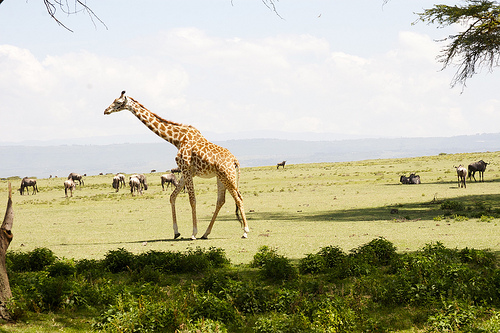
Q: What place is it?
A: It is a field.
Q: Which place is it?
A: It is a field.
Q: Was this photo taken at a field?
A: Yes, it was taken in a field.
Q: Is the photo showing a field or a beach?
A: It is showing a field.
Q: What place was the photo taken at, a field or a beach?
A: It was taken at a field.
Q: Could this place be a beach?
A: No, it is a field.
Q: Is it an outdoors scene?
A: Yes, it is outdoors.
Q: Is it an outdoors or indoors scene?
A: It is outdoors.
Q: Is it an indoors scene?
A: No, it is outdoors.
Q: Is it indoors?
A: No, it is outdoors.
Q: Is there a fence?
A: No, there are no fences.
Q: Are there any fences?
A: No, there are no fences.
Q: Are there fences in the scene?
A: No, there are no fences.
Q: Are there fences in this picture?
A: No, there are no fences.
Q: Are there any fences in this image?
A: No, there are no fences.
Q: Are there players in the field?
A: No, there is an animal in the field.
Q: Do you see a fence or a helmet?
A: No, there are no fences or helmets.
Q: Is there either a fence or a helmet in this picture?
A: No, there are no fences or helmets.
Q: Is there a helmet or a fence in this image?
A: No, there are no fences or helmets.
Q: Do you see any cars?
A: No, there are no cars.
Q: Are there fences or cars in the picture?
A: No, there are no cars or fences.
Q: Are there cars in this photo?
A: No, there are no cars.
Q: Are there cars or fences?
A: No, there are no cars or fences.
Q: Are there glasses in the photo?
A: No, there are no glasses.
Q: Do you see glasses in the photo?
A: No, there are no glasses.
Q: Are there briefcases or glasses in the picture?
A: No, there are no glasses or briefcases.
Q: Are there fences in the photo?
A: No, there are no fences.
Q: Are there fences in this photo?
A: No, there are no fences.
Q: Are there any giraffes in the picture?
A: Yes, there is a giraffe.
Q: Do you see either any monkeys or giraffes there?
A: Yes, there is a giraffe.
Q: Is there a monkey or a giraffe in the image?
A: Yes, there is a giraffe.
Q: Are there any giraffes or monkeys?
A: Yes, there is a giraffe.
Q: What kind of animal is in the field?
A: The animal is a giraffe.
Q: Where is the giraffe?
A: The giraffe is in the field.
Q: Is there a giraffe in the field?
A: Yes, there is a giraffe in the field.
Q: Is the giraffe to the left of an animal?
A: Yes, the giraffe is to the left of an animal.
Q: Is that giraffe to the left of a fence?
A: No, the giraffe is to the left of an animal.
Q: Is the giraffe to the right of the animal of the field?
A: No, the giraffe is to the left of the animal.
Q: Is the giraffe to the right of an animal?
A: Yes, the giraffe is to the right of an animal.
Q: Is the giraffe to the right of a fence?
A: No, the giraffe is to the right of an animal.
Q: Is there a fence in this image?
A: No, there are no fences.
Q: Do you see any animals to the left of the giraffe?
A: Yes, there is an animal to the left of the giraffe.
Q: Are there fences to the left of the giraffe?
A: No, there is an animal to the left of the giraffe.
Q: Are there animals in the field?
A: Yes, there is an animal in the field.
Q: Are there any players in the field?
A: No, there is an animal in the field.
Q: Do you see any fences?
A: No, there are no fences.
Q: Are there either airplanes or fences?
A: No, there are no fences or airplanes.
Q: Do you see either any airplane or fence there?
A: No, there are no fences or airplanes.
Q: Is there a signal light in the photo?
A: No, there are no traffic lights.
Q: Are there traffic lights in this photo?
A: No, there are no traffic lights.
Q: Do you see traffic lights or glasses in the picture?
A: No, there are no traffic lights or glasses.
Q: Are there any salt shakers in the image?
A: No, there are no salt shakers.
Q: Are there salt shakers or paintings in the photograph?
A: No, there are no salt shakers or paintings.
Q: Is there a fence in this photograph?
A: No, there are no fences.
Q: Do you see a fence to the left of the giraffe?
A: No, there is an animal to the left of the giraffe.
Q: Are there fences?
A: No, there are no fences.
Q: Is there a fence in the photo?
A: No, there are no fences.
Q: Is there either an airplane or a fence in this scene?
A: No, there are no fences or airplanes.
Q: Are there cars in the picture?
A: No, there are no cars.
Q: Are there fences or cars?
A: No, there are no cars or fences.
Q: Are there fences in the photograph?
A: No, there are no fences.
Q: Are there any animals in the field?
A: Yes, there is an animal in the field.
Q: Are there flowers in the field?
A: No, there is an animal in the field.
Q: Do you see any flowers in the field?
A: No, there is an animal in the field.